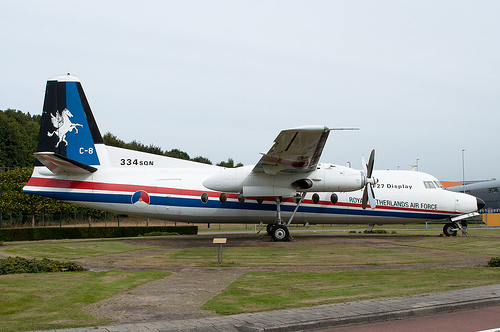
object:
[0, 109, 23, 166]
trees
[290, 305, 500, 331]
road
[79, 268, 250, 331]
sidewalk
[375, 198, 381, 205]
letters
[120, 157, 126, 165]
numbers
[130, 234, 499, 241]
landing strip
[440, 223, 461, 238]
front wheel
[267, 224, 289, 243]
back wheel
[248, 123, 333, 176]
right wing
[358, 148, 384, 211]
propellor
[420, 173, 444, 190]
cockpit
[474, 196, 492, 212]
nose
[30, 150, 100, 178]
horizontal stabilizer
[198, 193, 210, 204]
window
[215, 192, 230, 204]
window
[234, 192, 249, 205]
window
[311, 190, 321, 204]
window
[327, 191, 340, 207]
window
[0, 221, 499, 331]
grass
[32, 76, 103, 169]
tail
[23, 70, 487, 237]
airplane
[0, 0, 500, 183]
sky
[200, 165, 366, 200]
engine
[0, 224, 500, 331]
ground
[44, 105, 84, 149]
logo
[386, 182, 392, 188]
letter